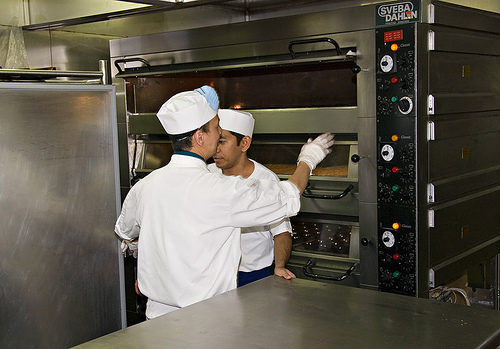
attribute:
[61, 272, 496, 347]
table — stainless, large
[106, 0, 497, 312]
ovens — large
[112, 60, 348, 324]
bakers —  Two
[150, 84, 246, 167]
hat — white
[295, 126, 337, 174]
glove — white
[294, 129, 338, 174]
hand — right hand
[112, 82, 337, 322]
man — white 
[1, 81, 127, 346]
door — stainless, steel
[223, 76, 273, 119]
light — green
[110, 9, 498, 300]
appliance — stainless, steel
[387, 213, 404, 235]
amber light —  amber colored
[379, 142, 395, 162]
knob — white 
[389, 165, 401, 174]
button — red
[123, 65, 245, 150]
hat — blue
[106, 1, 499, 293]
oven — Red